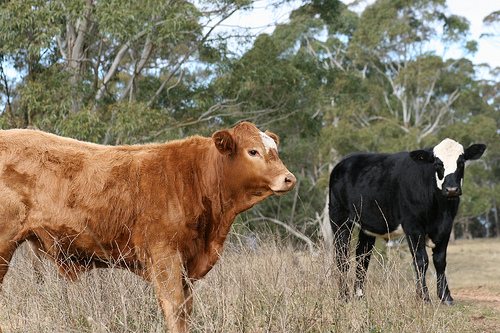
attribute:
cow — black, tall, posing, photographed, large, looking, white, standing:
[327, 138, 487, 305]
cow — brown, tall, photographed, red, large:
[1, 121, 298, 331]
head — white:
[411, 137, 487, 200]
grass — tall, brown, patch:
[0, 193, 450, 331]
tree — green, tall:
[1, 0, 318, 145]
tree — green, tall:
[294, 35, 372, 249]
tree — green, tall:
[272, 1, 359, 72]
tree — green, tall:
[328, 0, 499, 247]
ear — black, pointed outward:
[410, 149, 435, 165]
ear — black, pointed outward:
[465, 143, 487, 161]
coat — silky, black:
[327, 138, 486, 306]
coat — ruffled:
[1, 121, 298, 331]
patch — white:
[433, 138, 465, 190]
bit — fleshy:
[188, 188, 273, 281]